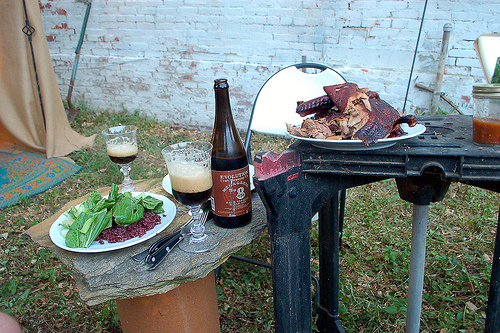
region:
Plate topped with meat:
[280, 74, 429, 159]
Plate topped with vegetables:
[45, 173, 179, 258]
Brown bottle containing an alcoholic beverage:
[204, 65, 256, 234]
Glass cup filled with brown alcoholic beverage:
[156, 130, 223, 255]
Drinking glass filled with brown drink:
[98, 118, 141, 204]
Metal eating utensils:
[142, 205, 217, 280]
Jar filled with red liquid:
[465, 77, 498, 152]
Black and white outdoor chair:
[238, 60, 355, 261]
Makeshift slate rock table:
[15, 133, 292, 331]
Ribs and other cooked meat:
[281, 73, 429, 145]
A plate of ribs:
[281, 79, 428, 144]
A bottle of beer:
[210, 76, 253, 229]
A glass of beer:
[160, 138, 220, 256]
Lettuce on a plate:
[61, 183, 165, 248]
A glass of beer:
[102, 120, 139, 192]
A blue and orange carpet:
[0, 147, 83, 209]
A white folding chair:
[226, 60, 349, 312]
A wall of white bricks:
[37, 0, 498, 134]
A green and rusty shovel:
[62, 0, 94, 127]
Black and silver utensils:
[132, 201, 209, 270]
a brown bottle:
[206, 75, 253, 225]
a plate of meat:
[285, 81, 424, 146]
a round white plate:
[48, 191, 175, 262]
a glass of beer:
[161, 140, 216, 257]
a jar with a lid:
[471, 83, 495, 148]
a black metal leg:
[261, 152, 317, 329]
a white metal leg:
[406, 188, 441, 325]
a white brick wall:
[118, 15, 180, 79]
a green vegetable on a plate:
[73, 185, 148, 249]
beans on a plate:
[101, 212, 172, 240]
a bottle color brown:
[205, 70, 257, 231]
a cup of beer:
[155, 130, 215, 255]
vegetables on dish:
[43, 182, 183, 260]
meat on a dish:
[276, 75, 433, 155]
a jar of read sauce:
[469, 75, 499, 149]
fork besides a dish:
[141, 199, 216, 274]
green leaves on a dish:
[62, 174, 137, 230]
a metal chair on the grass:
[237, 51, 371, 228]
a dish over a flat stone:
[7, 150, 282, 310]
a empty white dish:
[157, 158, 264, 208]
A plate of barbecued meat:
[282, 80, 422, 150]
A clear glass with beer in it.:
[160, 140, 220, 251]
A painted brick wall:
[36, 0, 498, 139]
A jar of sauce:
[469, 83, 498, 144]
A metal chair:
[215, 62, 349, 317]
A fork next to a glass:
[146, 207, 210, 269]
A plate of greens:
[49, 190, 178, 251]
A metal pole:
[405, 204, 434, 331]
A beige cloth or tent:
[0, 0, 97, 157]